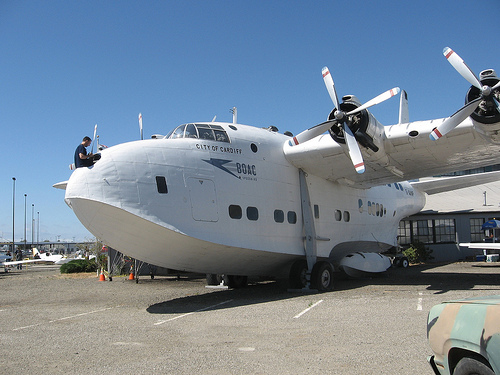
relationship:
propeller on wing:
[283, 50, 400, 178] [287, 59, 482, 183]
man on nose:
[71, 132, 103, 168] [63, 139, 140, 231]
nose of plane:
[63, 139, 140, 231] [47, 41, 494, 280]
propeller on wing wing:
[415, 36, 487, 152] [268, 50, 476, 191]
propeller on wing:
[287, 62, 404, 174] [282, 107, 498, 183]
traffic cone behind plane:
[129, 265, 134, 280] [56, 37, 498, 324]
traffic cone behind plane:
[98, 266, 106, 281] [56, 37, 498, 324]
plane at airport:
[18, 44, 498, 314] [21, 135, 481, 355]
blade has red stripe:
[322, 66, 339, 112] [322, 68, 329, 78]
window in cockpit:
[210, 123, 231, 143] [163, 122, 234, 143]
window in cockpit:
[194, 122, 214, 140] [163, 122, 234, 143]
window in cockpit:
[183, 120, 198, 140] [163, 122, 234, 143]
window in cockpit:
[171, 124, 186, 136] [163, 122, 234, 143]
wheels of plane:
[205, 253, 356, 291] [109, 83, 494, 304]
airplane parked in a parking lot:
[30, 44, 496, 289] [0, 260, 496, 373]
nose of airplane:
[63, 137, 140, 231] [30, 44, 496, 289]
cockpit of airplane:
[163, 122, 234, 143] [30, 44, 496, 289]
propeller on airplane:
[426, 94, 483, 143] [30, 44, 496, 289]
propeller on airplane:
[344, 85, 399, 116] [30, 44, 496, 289]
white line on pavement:
[10, 301, 129, 333] [1, 262, 499, 374]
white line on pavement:
[151, 293, 236, 326] [1, 262, 499, 374]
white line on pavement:
[289, 295, 327, 320] [1, 262, 499, 374]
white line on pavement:
[414, 285, 424, 314] [1, 262, 499, 374]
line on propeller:
[285, 132, 298, 149] [287, 62, 404, 174]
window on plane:
[227, 202, 244, 222] [47, 41, 494, 280]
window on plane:
[245, 205, 259, 218] [47, 41, 494, 280]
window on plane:
[274, 210, 286, 222] [47, 41, 494, 280]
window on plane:
[287, 210, 304, 230] [47, 41, 494, 280]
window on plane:
[334, 209, 344, 223] [47, 41, 494, 280]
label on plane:
[203, 158, 269, 184] [47, 41, 494, 280]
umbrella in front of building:
[463, 216, 498, 231] [396, 169, 498, 272]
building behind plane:
[396, 169, 498, 272] [47, 41, 494, 280]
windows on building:
[389, 210, 478, 245] [396, 169, 498, 272]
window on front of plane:
[160, 113, 231, 144] [47, 41, 494, 280]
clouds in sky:
[23, 167, 58, 216] [79, 27, 239, 113]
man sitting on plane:
[74, 136, 94, 168] [47, 41, 494, 280]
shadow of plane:
[146, 265, 498, 315] [47, 41, 494, 280]